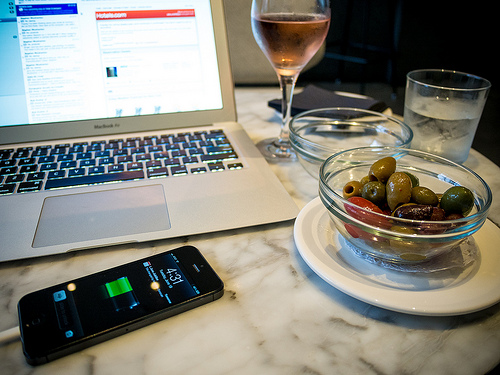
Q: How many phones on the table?
A: One.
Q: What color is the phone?
A: Black.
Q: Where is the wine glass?
A: On a table.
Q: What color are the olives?
A: Green.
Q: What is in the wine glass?
A: Wine.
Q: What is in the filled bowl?
A: Olives.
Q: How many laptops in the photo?
A: One.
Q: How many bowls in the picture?
A: Two.